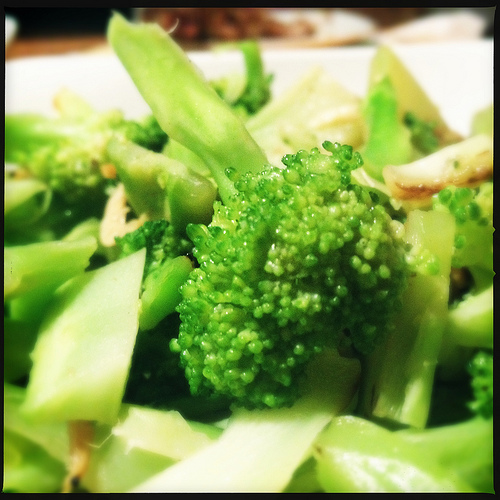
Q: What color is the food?
A: Green.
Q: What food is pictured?
A: Broccoli.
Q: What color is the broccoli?
A: Green.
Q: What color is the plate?
A: White.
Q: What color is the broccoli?
A: Green.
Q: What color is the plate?
A: White.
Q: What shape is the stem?
A: Flat.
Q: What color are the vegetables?
A: Green.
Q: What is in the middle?
A: A floret.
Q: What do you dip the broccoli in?
A: Ranch.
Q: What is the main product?
A: Broccoli.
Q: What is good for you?
A: Broccoli.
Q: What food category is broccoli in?
A: Vegetable.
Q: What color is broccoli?
A: Green.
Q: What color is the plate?
A: White.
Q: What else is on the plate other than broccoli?
A: Onions.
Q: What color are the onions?
A: White.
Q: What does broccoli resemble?
A: A small tree.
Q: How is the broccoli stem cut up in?
A: A triangle.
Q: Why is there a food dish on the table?
A: Someone's going to eat it.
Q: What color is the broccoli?
A: Green.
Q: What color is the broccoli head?
A: Green.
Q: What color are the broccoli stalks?
A: Green.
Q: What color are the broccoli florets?
A: Green.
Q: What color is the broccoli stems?
A: Green.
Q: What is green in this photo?
A: Broccoli.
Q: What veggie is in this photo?
A: Broccoli.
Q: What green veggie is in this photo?
A: Broccoli.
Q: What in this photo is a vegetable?
A: Broccoli.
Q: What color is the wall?
A: White.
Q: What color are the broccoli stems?
A: Green.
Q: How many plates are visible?
A: One.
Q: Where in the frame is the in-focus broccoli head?
A: In the center.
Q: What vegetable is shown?
A: Broccoli.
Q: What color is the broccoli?
A: Green.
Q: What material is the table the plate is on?
A: Wood.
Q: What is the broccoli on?
A: A plate.